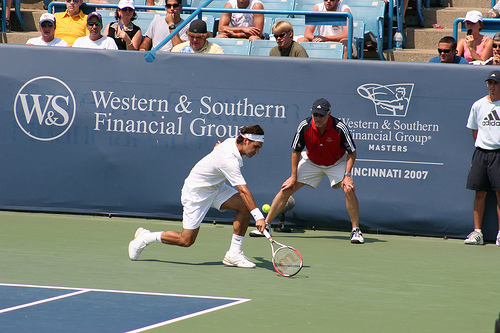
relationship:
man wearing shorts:
[253, 100, 373, 247] [295, 152, 356, 187]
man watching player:
[261, 81, 395, 248] [123, 114, 285, 269]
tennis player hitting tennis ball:
[122, 118, 313, 284] [258, 198, 277, 221]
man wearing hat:
[264, 92, 367, 242] [482, 65, 499, 82]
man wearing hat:
[459, 70, 499, 245] [308, 95, 331, 117]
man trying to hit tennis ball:
[122, 125, 284, 276] [260, 200, 273, 211]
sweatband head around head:
[234, 122, 265, 159] [235, 123, 271, 155]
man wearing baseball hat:
[297, 90, 363, 234] [309, 94, 331, 115]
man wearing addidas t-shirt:
[455, 55, 499, 237] [460, 89, 496, 145]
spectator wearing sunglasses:
[79, 4, 121, 43] [436, 42, 451, 54]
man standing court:
[463, 69, 498, 263] [0, 204, 498, 331]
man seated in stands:
[27, 9, 64, 55] [3, 4, 493, 202]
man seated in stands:
[21, 9, 64, 49] [7, 6, 497, 69]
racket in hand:
[258, 220, 308, 286] [253, 220, 278, 241]